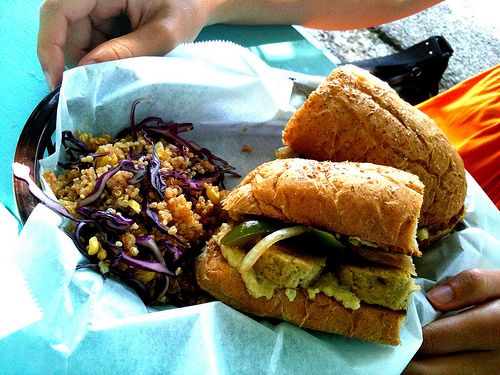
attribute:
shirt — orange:
[416, 57, 499, 208]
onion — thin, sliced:
[244, 221, 306, 284]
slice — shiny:
[219, 220, 266, 250]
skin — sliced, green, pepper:
[232, 222, 258, 235]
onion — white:
[239, 227, 303, 274]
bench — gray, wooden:
[43, 17, 495, 373]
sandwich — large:
[188, 150, 435, 362]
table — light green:
[0, 0, 499, 221]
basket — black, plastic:
[10, 44, 495, 369]